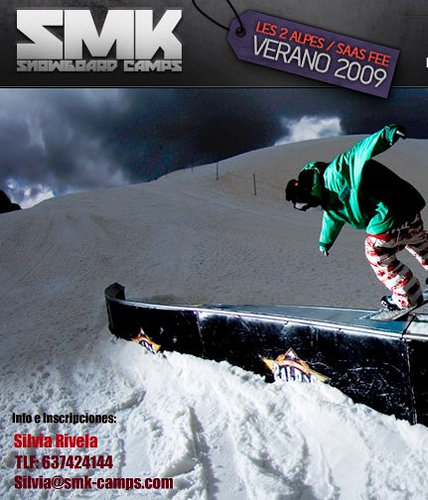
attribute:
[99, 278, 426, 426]
ski ramp — black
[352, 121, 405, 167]
arm — extended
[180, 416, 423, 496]
snow — white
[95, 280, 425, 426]
platform — black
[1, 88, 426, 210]
sky — blue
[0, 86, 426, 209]
clouds — black, grayish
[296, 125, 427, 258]
jacket — green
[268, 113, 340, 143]
cloud — white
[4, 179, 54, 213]
cloud — white